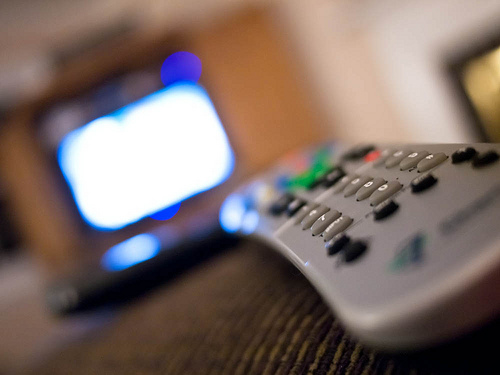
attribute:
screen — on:
[58, 81, 234, 231]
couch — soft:
[36, 239, 498, 367]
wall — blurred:
[6, 0, 498, 305]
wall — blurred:
[272, 1, 498, 145]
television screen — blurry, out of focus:
[53, 78, 236, 233]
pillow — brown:
[38, 240, 495, 371]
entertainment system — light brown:
[15, 85, 233, 291]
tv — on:
[61, 70, 254, 242]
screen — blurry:
[33, 87, 203, 225]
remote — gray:
[195, 104, 455, 367]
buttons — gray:
[273, 116, 454, 240]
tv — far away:
[39, 96, 234, 240]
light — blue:
[52, 94, 261, 232]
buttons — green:
[276, 53, 329, 198]